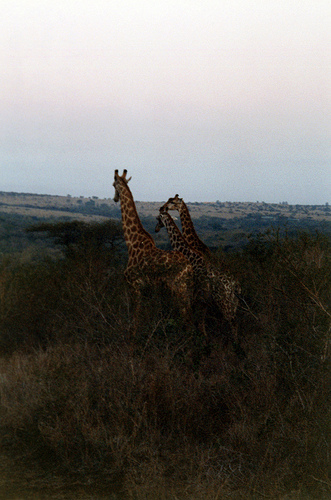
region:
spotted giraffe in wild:
[96, 160, 154, 285]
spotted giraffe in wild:
[152, 203, 201, 303]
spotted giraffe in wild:
[168, 183, 264, 330]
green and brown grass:
[30, 416, 101, 453]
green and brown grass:
[94, 418, 153, 447]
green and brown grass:
[161, 393, 222, 447]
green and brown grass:
[216, 399, 272, 463]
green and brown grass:
[262, 393, 309, 454]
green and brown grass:
[11, 351, 73, 417]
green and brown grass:
[78, 333, 142, 411]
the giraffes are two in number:
[105, 160, 228, 343]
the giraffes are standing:
[109, 170, 205, 300]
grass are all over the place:
[26, 345, 240, 473]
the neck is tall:
[111, 164, 140, 255]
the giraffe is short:
[151, 208, 179, 241]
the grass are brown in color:
[23, 341, 254, 455]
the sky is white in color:
[117, 55, 243, 134]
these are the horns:
[112, 166, 128, 178]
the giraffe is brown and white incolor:
[134, 231, 146, 246]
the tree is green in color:
[65, 216, 102, 240]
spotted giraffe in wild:
[164, 182, 202, 254]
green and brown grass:
[75, 422, 170, 476]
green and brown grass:
[127, 373, 176, 414]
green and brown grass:
[172, 391, 241, 432]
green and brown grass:
[194, 429, 234, 453]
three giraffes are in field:
[103, 164, 234, 377]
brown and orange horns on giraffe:
[98, 149, 129, 178]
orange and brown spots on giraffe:
[112, 200, 156, 273]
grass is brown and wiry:
[27, 295, 126, 456]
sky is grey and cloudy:
[22, 93, 162, 167]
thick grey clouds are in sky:
[21, 38, 167, 161]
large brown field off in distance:
[11, 194, 132, 244]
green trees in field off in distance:
[82, 195, 133, 221]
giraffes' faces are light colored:
[115, 175, 178, 210]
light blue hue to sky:
[67, 63, 239, 158]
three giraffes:
[107, 168, 241, 348]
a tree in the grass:
[42, 219, 117, 282]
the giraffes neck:
[118, 194, 132, 233]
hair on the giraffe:
[134, 202, 142, 225]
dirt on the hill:
[24, 192, 77, 218]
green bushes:
[215, 200, 261, 217]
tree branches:
[291, 267, 329, 313]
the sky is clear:
[85, 61, 268, 169]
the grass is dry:
[69, 403, 190, 478]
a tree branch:
[75, 288, 125, 342]